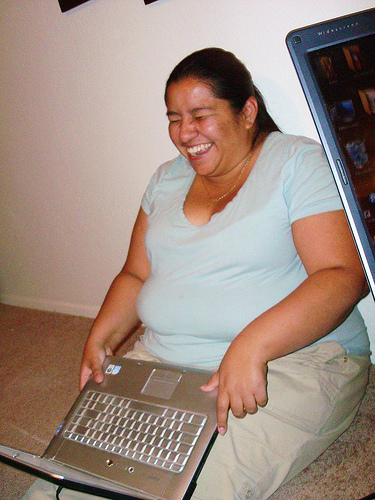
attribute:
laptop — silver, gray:
[0, 354, 216, 498]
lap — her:
[36, 352, 327, 498]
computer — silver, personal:
[2, 354, 231, 497]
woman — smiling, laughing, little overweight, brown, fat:
[22, 47, 369, 497]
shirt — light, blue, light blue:
[140, 131, 370, 364]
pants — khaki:
[21, 338, 370, 498]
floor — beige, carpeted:
[0, 304, 373, 498]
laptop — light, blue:
[285, 5, 374, 299]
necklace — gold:
[200, 150, 250, 201]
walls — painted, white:
[3, 75, 372, 364]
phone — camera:
[287, 7, 374, 298]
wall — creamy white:
[2, 0, 372, 362]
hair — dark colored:
[163, 47, 282, 134]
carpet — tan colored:
[0, 302, 362, 499]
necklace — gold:
[199, 145, 253, 202]